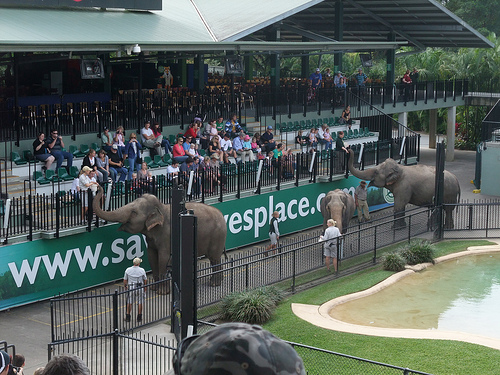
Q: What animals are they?
A: Elephants.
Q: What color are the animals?
A: Grey.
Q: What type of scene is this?
A: Outdoor.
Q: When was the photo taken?
A: Daytime.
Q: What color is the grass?
A: Green.